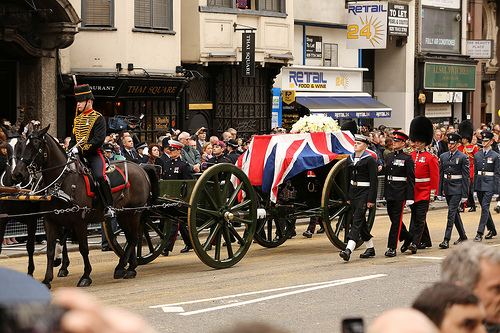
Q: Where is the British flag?
A: On casket.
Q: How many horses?
A: Two.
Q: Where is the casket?
A: On carriage.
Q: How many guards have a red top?
A: Two.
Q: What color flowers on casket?
A: White.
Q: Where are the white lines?
A: On street.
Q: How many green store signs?
A: One.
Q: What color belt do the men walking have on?
A: White.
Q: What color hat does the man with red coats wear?
A: Black.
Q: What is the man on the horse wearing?
A: Uniform.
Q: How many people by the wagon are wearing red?
A: One.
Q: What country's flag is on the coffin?
A: Britain.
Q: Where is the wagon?
A: On the road.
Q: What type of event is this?
A: Funeral.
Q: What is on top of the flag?
A: Flowers.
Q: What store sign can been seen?
A: Retail Food and Wine.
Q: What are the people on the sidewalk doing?
A: Paying respects.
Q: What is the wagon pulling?
A: Coffin.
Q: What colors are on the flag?
A: Red, white and blue.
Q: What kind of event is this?
A: Funeral.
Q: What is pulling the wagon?
A: Horses.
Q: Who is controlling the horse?
A: A man riding the on the horse's back.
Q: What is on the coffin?
A: A flag.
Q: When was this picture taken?
A: Daytime.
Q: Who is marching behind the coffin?
A: Soldiers.